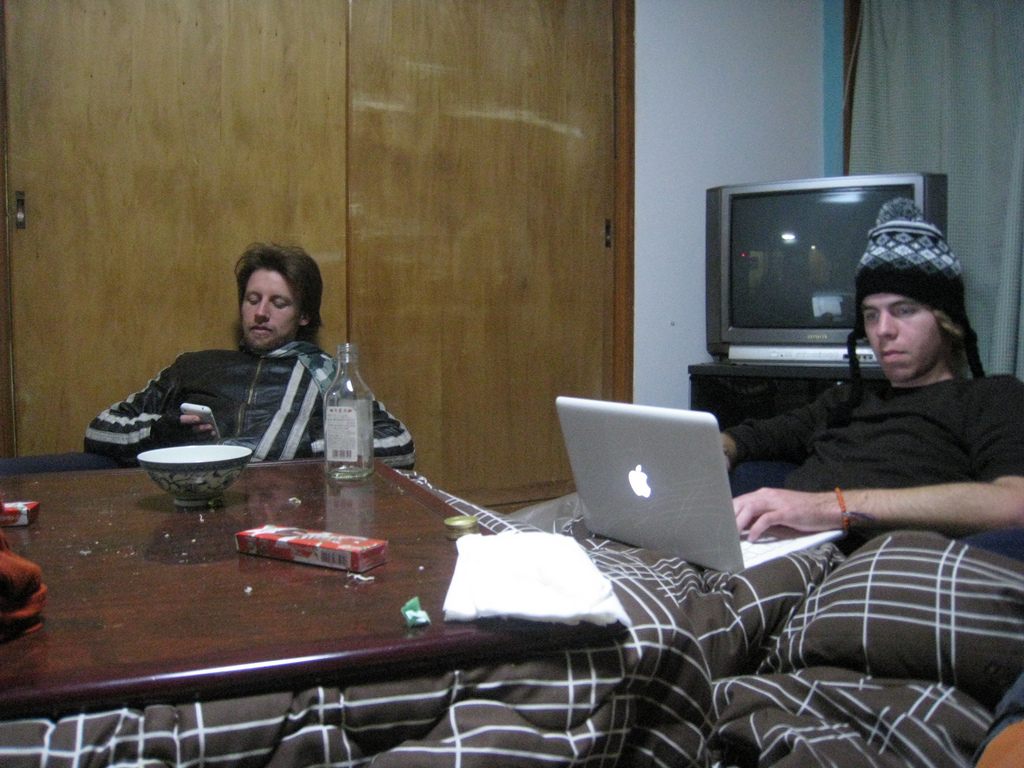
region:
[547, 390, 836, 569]
the silver apple laptop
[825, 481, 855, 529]
the orange bracelet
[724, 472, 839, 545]
the hand of the man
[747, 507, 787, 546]
the finger on the hand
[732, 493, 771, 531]
the finger on the hand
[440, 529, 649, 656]
the white napkin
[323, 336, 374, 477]
the empty clear bottle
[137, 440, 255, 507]
the blue and white bowl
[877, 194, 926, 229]
the grey pom pom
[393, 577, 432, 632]
garbage on the wood table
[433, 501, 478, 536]
garbage on the wood table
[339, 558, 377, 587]
garbage on the wood table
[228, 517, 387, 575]
garbage on the wood table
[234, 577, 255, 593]
garbage on the wood table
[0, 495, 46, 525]
garbage on the wood table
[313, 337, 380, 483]
garbage on the wood table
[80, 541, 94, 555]
garbage on the wood table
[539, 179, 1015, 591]
A man typing on a laptop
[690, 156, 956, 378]
A television set is turned off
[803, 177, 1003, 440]
A black, gray and white bonnet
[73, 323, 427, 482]
White stripes on a black jacket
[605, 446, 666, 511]
Apple symbol on a laptop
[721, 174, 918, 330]
Reflections on a TV screen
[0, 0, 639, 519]
Brown wooden closet doors are closed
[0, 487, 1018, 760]
White stripes on a brown blanket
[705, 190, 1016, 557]
Man has on a black shirt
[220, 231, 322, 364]
A man has his eyes closed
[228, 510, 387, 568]
garbage on the wood table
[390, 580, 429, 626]
garbage on the wood table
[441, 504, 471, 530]
garbage on the wood table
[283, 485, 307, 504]
garbage on the wood table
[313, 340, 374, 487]
garbage on the wood table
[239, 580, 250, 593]
garbage on the wood table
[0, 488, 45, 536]
garbage on the wood table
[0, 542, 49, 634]
garbage on the wood table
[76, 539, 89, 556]
garbage on the wood table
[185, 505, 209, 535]
garbage on the wood table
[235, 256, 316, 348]
person has a head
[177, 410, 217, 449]
person has a hand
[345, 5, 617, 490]
wood panel is brown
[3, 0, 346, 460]
wood panel is brown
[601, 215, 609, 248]
door has a handle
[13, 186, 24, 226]
door has a handle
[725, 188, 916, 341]
tv has a glass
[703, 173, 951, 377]
tv is gray and black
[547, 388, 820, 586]
silver laptop computer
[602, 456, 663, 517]
white apple on silver computer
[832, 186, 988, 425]
black and white ski hat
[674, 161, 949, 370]
silver tv on table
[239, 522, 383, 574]
red cigarette box on table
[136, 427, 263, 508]
empty white bowl on table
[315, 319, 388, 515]
empty liquor bottle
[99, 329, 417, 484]
black and white striped leather jacket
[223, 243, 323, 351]
brown mullet hair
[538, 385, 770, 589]
back lid of laptop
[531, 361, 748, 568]
back lid of laptop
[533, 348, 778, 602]
back lid of laptop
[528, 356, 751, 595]
back lid of laptop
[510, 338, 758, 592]
back lid of laptop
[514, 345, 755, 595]
back lid of laptop